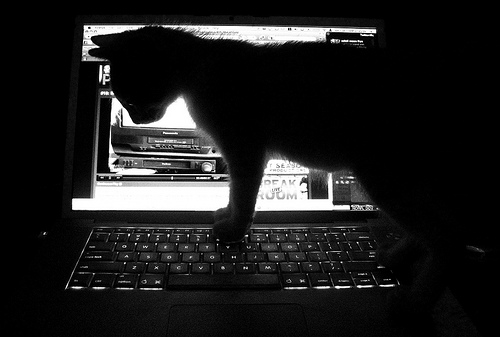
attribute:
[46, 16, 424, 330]
laptop — on, shining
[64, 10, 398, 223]
monitor — shining, lit, illuminated, bright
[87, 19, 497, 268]
cat — looking down, in darkness, illuminated, dark, in the dark, sideways on, black, white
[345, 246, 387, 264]
button — back space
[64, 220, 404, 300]
keyboard — lit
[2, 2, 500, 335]
room — dark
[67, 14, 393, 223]
screen — lit, illuminated, bright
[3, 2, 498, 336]
image — black, white